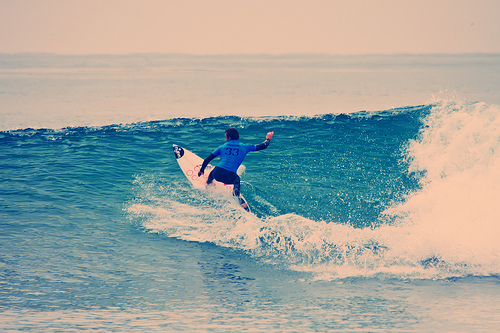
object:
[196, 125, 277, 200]
man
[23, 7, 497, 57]
sky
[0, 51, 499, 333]
water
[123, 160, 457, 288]
wake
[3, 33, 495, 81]
horizon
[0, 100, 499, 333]
blue water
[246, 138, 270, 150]
arm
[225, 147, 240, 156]
number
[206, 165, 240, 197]
pant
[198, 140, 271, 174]
blue shirt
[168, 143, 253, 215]
surfboard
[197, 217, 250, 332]
reflection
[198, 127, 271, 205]
wetsuit